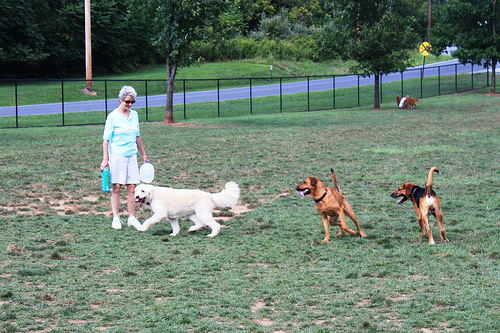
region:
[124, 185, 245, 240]
White dog in a field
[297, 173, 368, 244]
Brown dog running in field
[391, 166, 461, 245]
Black and brown dog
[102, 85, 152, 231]
Woman standing in a field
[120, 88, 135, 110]
Woman wearing black sunglasses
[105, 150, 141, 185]
Woman wearing white shorts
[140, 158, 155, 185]
White bottle with blue top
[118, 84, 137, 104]
Short thick gray hair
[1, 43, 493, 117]
Blue tarmacked road beside field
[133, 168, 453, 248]
Dogs playing in the field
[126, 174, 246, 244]
big white fluffy dog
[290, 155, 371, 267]
brown dog with black collar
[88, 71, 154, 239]
woman wearing blue shirt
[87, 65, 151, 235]
woman wearing white shorts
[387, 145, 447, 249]
brown and black dog playing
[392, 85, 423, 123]
two brown dogs playing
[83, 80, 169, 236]
woman carrying water jug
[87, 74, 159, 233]
woman wearing dark sunglasses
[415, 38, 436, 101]
yellow sign on pole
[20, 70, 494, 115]
black fence around park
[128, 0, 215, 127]
small tree with mud on trunk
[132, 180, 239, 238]
a medium white dog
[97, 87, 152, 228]
an elderly lady at dog park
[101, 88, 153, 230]
lady in light clothing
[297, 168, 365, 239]
a brown medium dogs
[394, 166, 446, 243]
a brown and black medium dog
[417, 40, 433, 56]
a yellow street sign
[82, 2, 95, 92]
light colored pole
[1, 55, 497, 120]
street beside dog park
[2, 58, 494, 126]
a black chain link fence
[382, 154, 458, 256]
house dog playing in park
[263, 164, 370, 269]
brown dog running atop green grass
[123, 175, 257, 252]
white dog with bushy tail walking in park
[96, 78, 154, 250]
older adult human woman with water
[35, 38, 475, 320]
park scene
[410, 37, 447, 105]
railroad crossing warning sign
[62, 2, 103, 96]
telephone pole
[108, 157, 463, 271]
three dog friends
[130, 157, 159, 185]
one gallon jug of water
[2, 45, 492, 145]
tall fence separating street and park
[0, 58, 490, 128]
a balk fence surrounding a park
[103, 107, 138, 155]
woman wearing a light blue shirt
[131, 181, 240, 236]
a white dog standing in the grass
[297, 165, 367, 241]
a brown dog running in a park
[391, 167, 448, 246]
a brown and black dog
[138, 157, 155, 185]
a woman holding a white frisbee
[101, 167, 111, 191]
a woman holding a blue plastic bottle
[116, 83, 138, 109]
a woman with light gray hair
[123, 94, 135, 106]
a woman wearing black sunglasses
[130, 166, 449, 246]
three dogs playing in a park